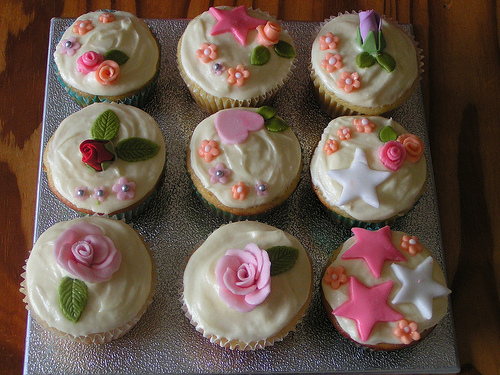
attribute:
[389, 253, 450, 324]
star — white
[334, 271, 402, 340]
star — pink, fondant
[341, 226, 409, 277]
star — pink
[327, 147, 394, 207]
star — white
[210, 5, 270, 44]
star — pink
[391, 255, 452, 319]
star — white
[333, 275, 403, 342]
star — pink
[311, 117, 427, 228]
cupcake — frosted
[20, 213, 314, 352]
cupcakes — decorated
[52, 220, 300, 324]
rose designs — pink, light pink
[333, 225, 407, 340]
two stars — pink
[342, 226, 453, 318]
stars — pink, white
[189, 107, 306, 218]
cupcake — white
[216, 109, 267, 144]
heart design — pink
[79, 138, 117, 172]
rose design — red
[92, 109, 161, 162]
leaves — green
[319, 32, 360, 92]
floral design — orange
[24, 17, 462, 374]
tray — textured, silver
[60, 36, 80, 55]
pink flower — light, icing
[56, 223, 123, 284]
rose — pink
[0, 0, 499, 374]
table — wooden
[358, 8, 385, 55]
rose bud — purple